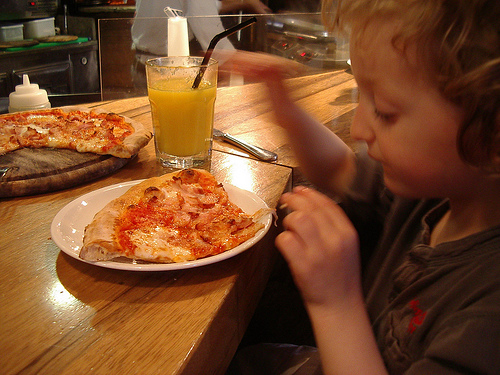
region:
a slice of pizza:
[49, 163, 313, 289]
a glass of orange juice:
[125, 41, 260, 208]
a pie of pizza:
[3, 83, 160, 180]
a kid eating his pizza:
[247, 8, 497, 343]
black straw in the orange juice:
[115, 13, 271, 168]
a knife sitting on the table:
[198, 111, 292, 168]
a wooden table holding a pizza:
[0, 238, 278, 366]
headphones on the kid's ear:
[397, 97, 499, 204]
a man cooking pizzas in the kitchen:
[139, 0, 291, 94]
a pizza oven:
[243, 18, 354, 94]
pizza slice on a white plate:
[77, 165, 277, 268]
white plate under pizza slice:
[49, 177, 272, 272]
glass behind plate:
[144, 54, 219, 169]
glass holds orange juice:
[146, 77, 217, 158]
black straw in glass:
[189, 16, 257, 88]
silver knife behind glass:
[210, 126, 277, 162]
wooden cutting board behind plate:
[0, 145, 137, 198]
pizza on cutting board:
[0, 105, 153, 159]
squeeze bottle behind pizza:
[7, 72, 51, 112]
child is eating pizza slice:
[198, 0, 498, 374]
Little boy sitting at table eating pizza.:
[63, 14, 468, 343]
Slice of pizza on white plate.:
[55, 166, 277, 278]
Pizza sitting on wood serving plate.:
[1, 103, 141, 196]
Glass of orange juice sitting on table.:
[141, 53, 236, 174]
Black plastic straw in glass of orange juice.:
[191, 6, 266, 90]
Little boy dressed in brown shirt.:
[360, 203, 496, 371]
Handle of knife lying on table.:
[218, 126, 290, 176]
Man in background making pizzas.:
[128, 3, 332, 93]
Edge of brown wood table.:
[36, 276, 243, 373]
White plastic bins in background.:
[2, 14, 66, 44]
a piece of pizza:
[91, 211, 233, 256]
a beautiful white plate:
[61, 209, 82, 246]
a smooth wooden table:
[26, 326, 191, 366]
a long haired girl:
[446, 87, 498, 164]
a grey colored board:
[9, 153, 111, 183]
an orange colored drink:
[151, 95, 221, 162]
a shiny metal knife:
[224, 127, 279, 174]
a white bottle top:
[8, 86, 55, 113]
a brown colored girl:
[368, 95, 447, 199]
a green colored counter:
[35, 43, 57, 50]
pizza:
[3, 100, 150, 200]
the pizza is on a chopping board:
[1, 106, 158, 193]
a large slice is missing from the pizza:
[2, 102, 157, 187]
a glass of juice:
[143, 31, 243, 168]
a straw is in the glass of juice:
[141, 26, 247, 170]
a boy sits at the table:
[251, 5, 496, 370]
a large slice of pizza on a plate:
[57, 159, 267, 284]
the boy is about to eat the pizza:
[84, 11, 496, 368]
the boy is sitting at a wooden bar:
[25, 11, 474, 363]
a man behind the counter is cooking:
[125, 5, 320, 85]